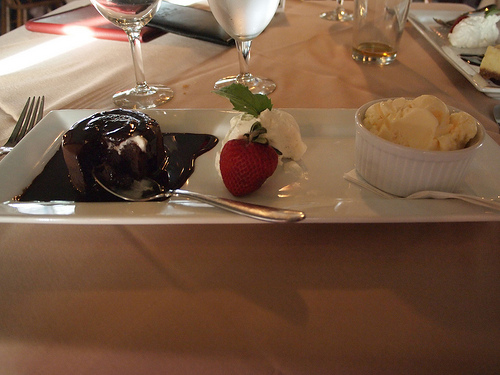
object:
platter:
[0, 109, 500, 225]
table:
[0, 0, 500, 375]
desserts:
[361, 94, 479, 151]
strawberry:
[219, 121, 283, 197]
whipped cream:
[215, 108, 307, 163]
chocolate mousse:
[11, 108, 219, 202]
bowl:
[352, 98, 486, 198]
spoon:
[91, 167, 306, 223]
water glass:
[207, 0, 281, 97]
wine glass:
[90, 0, 175, 108]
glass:
[351, 0, 412, 66]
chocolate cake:
[62, 108, 170, 202]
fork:
[0, 95, 45, 155]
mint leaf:
[209, 83, 273, 118]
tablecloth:
[0, 0, 499, 374]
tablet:
[25, 3, 168, 43]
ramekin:
[378, 102, 445, 129]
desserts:
[448, 6, 500, 82]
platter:
[399, 4, 499, 99]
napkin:
[344, 166, 500, 209]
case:
[146, 0, 237, 46]